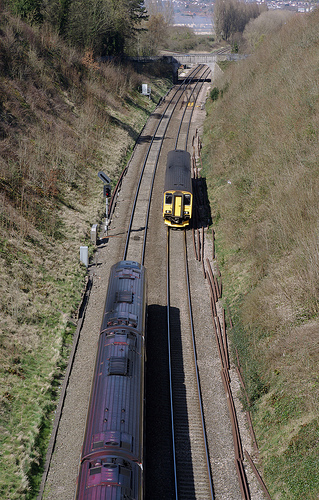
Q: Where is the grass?
A: On the hillsides.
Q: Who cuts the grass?
A: A work crew.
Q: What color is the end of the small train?
A: Yellow.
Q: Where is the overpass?
A: Straight ahead.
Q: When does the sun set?
A: In the late evening.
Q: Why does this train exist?
A: To transport passengers.